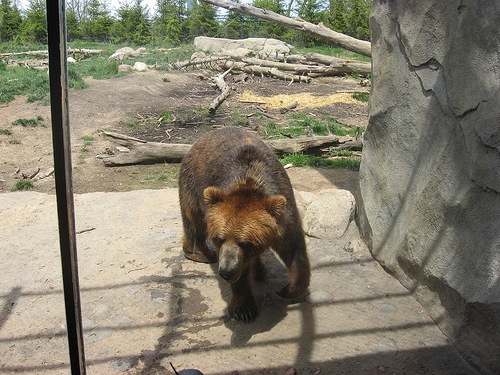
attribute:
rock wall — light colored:
[387, 28, 482, 142]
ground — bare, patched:
[113, 213, 135, 232]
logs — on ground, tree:
[206, 66, 277, 119]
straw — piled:
[257, 89, 373, 112]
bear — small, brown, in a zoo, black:
[173, 132, 317, 316]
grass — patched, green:
[18, 68, 25, 91]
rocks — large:
[113, 43, 157, 90]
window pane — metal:
[23, 40, 79, 181]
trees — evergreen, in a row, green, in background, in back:
[71, 7, 240, 40]